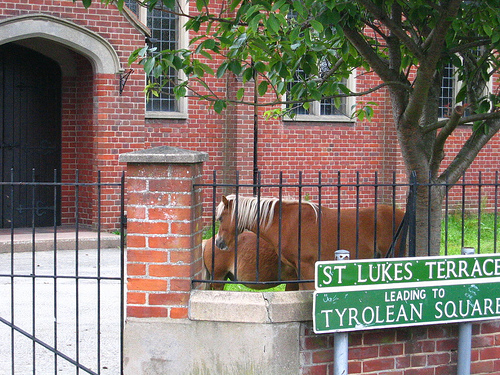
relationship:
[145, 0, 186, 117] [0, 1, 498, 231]
window on building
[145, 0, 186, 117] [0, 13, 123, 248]
window on building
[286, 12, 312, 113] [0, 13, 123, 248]
window on building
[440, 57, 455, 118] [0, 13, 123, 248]
window on building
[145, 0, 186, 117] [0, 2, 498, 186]
window on building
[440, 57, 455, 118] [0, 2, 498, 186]
window on building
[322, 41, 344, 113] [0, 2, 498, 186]
window on building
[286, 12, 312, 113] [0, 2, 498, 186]
window on building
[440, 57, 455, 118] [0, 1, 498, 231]
window on building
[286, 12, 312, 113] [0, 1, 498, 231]
window on building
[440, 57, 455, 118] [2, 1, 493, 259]
window on building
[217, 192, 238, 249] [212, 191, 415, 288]
head of horse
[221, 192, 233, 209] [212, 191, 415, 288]
ear of horse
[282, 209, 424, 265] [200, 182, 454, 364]
body of horse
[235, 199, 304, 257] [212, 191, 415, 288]
neck of horse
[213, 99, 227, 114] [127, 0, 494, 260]
leaf of tree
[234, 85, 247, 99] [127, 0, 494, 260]
leaf of tree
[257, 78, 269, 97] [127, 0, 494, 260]
leaf of tree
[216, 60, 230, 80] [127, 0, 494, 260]
leaf of tree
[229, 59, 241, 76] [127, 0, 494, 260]
leaf of tree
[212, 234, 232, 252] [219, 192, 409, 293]
mouth of horse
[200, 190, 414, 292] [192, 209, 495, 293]
horses on lawn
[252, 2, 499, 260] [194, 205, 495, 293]
tree in yard